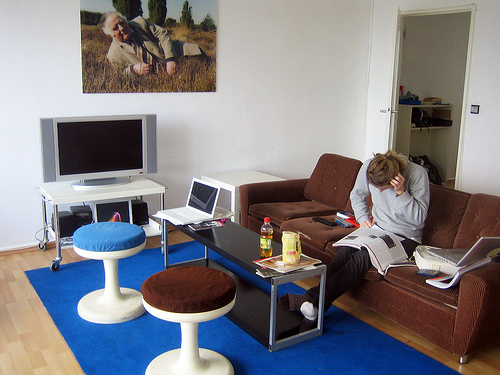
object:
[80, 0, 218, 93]
picture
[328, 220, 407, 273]
magazine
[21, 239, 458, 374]
rug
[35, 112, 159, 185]
television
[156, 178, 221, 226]
laptop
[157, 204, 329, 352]
table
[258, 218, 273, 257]
bottle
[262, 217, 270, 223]
cap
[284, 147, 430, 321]
man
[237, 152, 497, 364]
couch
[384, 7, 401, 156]
door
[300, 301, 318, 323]
sock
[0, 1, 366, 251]
wall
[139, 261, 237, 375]
stool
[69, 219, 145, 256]
stool cushion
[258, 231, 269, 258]
drink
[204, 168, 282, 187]
end table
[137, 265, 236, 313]
cushion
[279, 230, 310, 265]
container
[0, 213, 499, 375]
floor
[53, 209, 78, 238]
speakers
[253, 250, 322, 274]
magazines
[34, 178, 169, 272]
stand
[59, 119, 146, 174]
screen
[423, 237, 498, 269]
laptop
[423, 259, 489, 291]
book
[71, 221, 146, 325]
stools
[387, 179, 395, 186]
fingers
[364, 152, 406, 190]
hair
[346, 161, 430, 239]
shirt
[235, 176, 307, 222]
arm